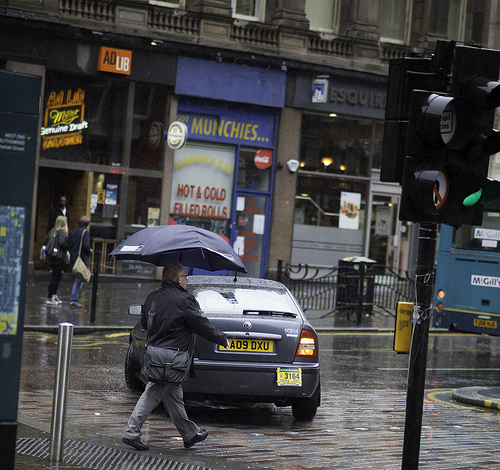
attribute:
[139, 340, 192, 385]
bag — black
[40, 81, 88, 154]
sign — neon, orange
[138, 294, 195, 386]
satchel — black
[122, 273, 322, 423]
car — gray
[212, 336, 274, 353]
license plate — yellow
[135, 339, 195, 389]
satchel — grey